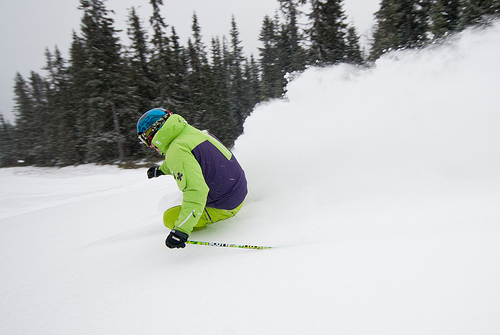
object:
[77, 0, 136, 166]
tree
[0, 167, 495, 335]
ground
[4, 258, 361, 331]
snow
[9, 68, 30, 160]
tree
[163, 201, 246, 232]
pants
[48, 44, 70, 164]
tree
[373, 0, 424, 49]
trees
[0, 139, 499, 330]
field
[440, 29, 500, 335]
snow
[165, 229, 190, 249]
gloves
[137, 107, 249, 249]
falling down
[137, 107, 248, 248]
man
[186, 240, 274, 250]
skiing sticks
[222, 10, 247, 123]
tree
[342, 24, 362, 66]
tree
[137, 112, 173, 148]
goggles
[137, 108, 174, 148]
helmet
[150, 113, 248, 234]
jacket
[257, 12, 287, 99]
tree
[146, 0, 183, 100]
trees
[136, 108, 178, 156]
head